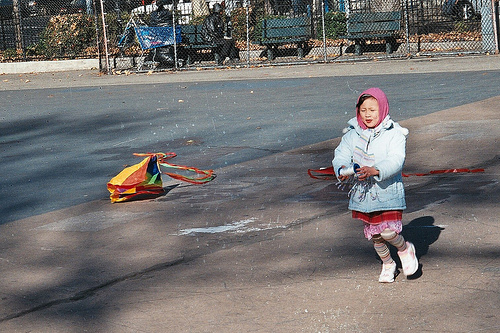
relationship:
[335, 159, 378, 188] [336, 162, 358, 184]
hands holding spool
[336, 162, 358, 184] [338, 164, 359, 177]
spool has spool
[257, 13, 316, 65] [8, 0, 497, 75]
bench behind fence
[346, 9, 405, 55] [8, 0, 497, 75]
bench behind fence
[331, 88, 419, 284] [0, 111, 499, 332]
child casting shadows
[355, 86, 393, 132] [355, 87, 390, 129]
head with cap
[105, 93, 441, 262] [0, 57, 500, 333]
leaves on road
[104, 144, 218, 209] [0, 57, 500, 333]
kite on road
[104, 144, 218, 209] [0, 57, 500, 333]
kite crashed to road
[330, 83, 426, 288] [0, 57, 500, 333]
child on road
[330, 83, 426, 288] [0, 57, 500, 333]
child walking on road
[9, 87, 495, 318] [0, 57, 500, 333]
shadows on road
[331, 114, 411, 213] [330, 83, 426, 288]
coat on child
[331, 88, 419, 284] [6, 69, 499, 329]
child on road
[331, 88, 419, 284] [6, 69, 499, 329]
child running on road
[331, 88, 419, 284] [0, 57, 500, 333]
child on road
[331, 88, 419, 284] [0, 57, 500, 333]
child running on road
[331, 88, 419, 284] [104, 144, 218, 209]
child flying kite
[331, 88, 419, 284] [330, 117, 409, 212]
child wearing coat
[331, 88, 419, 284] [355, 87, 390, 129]
child wearing cap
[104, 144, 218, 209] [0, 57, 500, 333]
kite close to road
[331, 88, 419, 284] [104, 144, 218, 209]
child with kite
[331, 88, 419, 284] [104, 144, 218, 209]
child tries to fly kite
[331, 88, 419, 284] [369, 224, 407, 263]
child has socks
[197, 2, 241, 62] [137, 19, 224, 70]
person on bench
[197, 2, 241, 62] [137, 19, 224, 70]
person sitting on bench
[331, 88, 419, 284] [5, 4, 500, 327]
child playing in park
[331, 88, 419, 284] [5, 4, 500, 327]
child in park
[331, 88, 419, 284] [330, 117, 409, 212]
child wears coat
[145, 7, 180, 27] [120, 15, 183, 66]
garbage bag in cart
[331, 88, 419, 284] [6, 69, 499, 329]
child in road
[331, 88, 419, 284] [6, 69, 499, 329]
child standing in road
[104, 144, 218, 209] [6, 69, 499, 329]
kite in road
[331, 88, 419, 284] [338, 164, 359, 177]
child holding spool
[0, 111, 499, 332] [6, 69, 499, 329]
shadows in road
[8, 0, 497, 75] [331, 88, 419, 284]
fence behind child